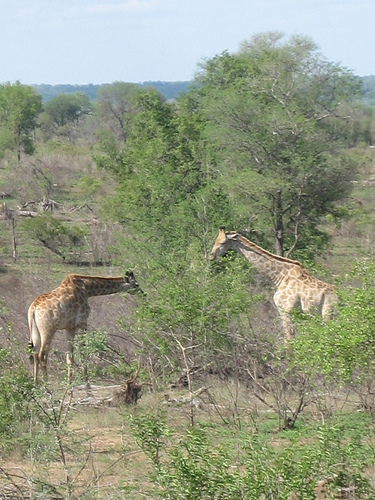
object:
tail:
[30, 304, 39, 363]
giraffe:
[25, 270, 143, 385]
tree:
[206, 32, 363, 256]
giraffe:
[206, 225, 341, 344]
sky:
[1, 2, 375, 88]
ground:
[0, 71, 374, 499]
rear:
[26, 299, 49, 334]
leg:
[63, 329, 76, 404]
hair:
[67, 274, 126, 282]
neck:
[74, 273, 125, 298]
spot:
[44, 301, 54, 309]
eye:
[132, 280, 136, 288]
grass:
[1, 142, 374, 499]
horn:
[125, 270, 136, 280]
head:
[120, 269, 148, 302]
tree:
[288, 261, 374, 417]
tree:
[0, 84, 46, 161]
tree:
[113, 411, 374, 499]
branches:
[238, 351, 312, 432]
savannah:
[2, 31, 374, 499]